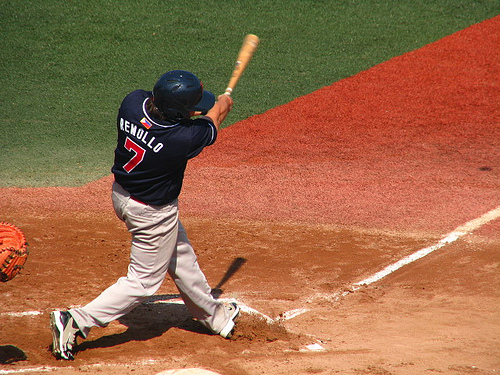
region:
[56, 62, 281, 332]
batter swinging at ball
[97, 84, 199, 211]
batter has blue jersey on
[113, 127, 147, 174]
blue jersey has red 7 on back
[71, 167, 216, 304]
batter is wearing white pants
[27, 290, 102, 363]
batter is wearing white and blue shoes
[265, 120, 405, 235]
baseball diamond is of orange sand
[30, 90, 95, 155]
grass by diamond is green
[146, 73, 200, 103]
batter is wearing blue helmet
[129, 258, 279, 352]
shadow cast by batter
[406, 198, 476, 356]
white line on red baseball diamond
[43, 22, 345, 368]
The man is playing baseball.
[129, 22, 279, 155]
The man is swinging a bat.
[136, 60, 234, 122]
The man wears a helmet.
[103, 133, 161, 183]
The number 7 is on the jersey.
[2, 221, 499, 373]
The field is made of dirt.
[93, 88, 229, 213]
The jersey is blue.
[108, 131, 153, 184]
The number 7 is red.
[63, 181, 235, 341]
The player wears tan pants.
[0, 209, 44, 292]
A glove is visible behind the player.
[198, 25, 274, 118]
The bat is made of wood.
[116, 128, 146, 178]
red number 7 on the back of the batters blue shirt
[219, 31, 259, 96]
bat which the batter is using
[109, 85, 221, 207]
dark blue shirt with red number and his last name in white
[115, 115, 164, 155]
name on the back of the batters shirt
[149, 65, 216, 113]
batters helmet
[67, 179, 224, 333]
light tan pants the batter is wearing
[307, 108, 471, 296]
red clay dirt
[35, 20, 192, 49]
field of green grass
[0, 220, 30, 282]
baseball glove of the person behind the batter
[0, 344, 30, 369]
shadow of baseball glove behind batter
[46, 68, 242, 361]
Baseball batter swinging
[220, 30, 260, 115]
Brown bat being swung by baseball batter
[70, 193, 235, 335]
White pants on baseball batter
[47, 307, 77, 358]
White and black shoe of baseball batter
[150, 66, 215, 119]
Blue helmet of baseball batter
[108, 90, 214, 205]
Blue jersey no. "7" on baseball batter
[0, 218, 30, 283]
Light brown mitt of not pictured baseball catcher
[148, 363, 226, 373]
Part of home plate on a baseball field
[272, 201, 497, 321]
Part of white chalk third baseline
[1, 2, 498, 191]
Green grass perimeter of a baseball field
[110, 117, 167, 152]
player's name on jersey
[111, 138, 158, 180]
number 7 on jersey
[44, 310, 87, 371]
right foot of player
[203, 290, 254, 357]
left foot of player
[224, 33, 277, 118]
wooden bat being swung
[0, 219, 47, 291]
brown glove of catcher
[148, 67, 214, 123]
navy blue batting helmet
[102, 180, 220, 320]
grey uniform pants of player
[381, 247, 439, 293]
white line on field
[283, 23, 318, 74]
patch of green grass